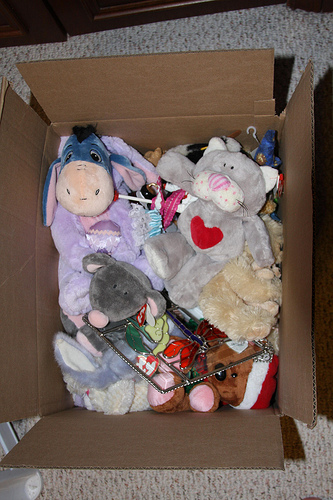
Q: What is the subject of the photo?
A: Toys.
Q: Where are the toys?
A: Cardboard box.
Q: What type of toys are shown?
A: Stuffed animal.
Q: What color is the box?
A: Brown.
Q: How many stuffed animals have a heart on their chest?
A: One.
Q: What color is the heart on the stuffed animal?
A: Red.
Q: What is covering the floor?
A: Carpet.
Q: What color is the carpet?
A: White.